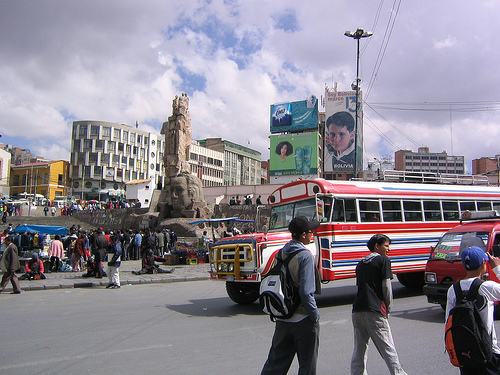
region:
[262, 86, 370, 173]
group of advertising billboards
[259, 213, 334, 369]
man wearing backpack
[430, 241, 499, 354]
boy in blue baseball cap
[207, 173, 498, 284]
red white and blue striped bus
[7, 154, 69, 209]
yellow house with tile roof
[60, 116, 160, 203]
multi-story apartment building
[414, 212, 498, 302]
small red passenger vehicle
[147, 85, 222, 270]
stone statue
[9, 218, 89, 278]
street vendor booth with blue canopy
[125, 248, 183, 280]
person sitting on sidewalk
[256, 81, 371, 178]
billboards with pictures of people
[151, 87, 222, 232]
sculpture mad of stone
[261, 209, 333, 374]
boy with backpack walking down the street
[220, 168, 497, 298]
colorful red and blue bus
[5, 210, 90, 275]
vendor selling wares on the street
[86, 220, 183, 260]
people on sidewalk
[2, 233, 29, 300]
man in suit walking in street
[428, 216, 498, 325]
red car driving down the street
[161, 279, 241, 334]
shadow of colorful bus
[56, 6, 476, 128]
Large gray and white clouds.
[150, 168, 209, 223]
Large bust of a man.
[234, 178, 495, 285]
A colorful bus with red, white and blue stripes.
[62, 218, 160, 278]
Large crowd of people.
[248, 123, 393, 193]
A bill board in the background.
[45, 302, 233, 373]
A gray city street.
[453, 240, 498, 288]
A young man with a blue baseball cap.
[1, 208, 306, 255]
small market serving people.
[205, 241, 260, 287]
The bus has a yellow grill.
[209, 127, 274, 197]
The building is a older green structure.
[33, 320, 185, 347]
faint white line on street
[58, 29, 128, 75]
fluffy white clouds in the sky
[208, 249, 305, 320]
blue and white back pack on man's back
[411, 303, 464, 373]
orange portion of back pack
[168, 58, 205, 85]
blue section of skies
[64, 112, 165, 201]
round white and gray building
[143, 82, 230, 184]
large tan statue on street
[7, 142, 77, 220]
orange building with white stripes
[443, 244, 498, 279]
blue cap on man's head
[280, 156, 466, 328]
large red white and blue bus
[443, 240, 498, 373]
person with blue cap and backpack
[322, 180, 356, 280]
side of red, white, and blue bus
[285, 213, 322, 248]
man with glasses and black cap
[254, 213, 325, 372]
man with black cap and white backpack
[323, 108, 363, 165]
face of boy on billboard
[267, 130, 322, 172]
green billboard with female with dark hair on it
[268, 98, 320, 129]
blue and white billboard with ad on it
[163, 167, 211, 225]
big stone bust of a man's head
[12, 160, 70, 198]
a yellow building with pink roof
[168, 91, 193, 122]
top of a monument with three figures on it